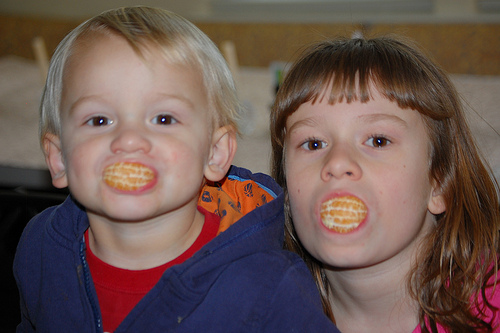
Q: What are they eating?
A: Oranges.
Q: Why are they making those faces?
A: To be silly.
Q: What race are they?
A: White.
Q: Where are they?
A: At the living room.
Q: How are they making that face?
A: By sectioning of a skinned side of the orange in their mouth.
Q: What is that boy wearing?
A: A thin hoodie.